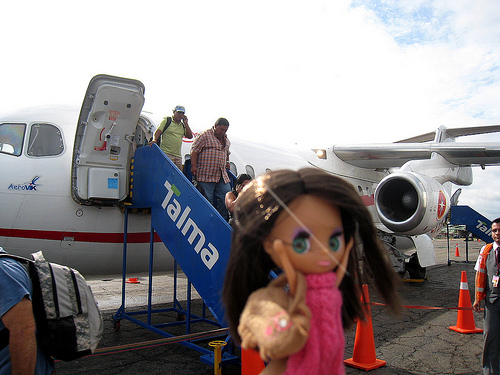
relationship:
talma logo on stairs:
[136, 155, 245, 285] [134, 133, 263, 329]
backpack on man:
[141, 118, 187, 165] [154, 103, 194, 172]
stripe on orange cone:
[458, 280, 472, 292] [437, 259, 487, 342]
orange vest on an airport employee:
[470, 223, 499, 309] [473, 215, 500, 366]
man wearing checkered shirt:
[192, 118, 232, 222] [193, 127, 229, 182]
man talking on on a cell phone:
[154, 103, 194, 172] [181, 115, 189, 121]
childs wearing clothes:
[224, 165, 406, 374] [238, 273, 343, 373]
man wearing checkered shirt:
[189, 116, 235, 202] [193, 129, 235, 182]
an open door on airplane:
[70, 74, 145, 207] [0, 69, 497, 340]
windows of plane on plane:
[2, 115, 69, 174] [0, 79, 493, 342]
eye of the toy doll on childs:
[290, 225, 315, 259] [224, 165, 406, 374]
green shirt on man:
[153, 112, 193, 162] [154, 103, 191, 165]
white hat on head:
[169, 105, 188, 122] [167, 103, 194, 126]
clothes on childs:
[238, 273, 343, 373] [224, 165, 406, 374]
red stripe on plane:
[0, 221, 163, 264] [0, 79, 493, 342]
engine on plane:
[376, 172, 463, 235] [296, 113, 496, 267]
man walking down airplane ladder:
[192, 118, 232, 222] [117, 142, 283, 363]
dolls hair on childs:
[222, 165, 398, 345] [224, 165, 406, 374]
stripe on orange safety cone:
[358, 302, 377, 320] [346, 284, 384, 370]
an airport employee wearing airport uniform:
[473, 215, 500, 366] [466, 243, 499, 370]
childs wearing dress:
[224, 165, 406, 374] [249, 273, 350, 373]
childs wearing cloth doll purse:
[217, 165, 406, 374] [237, 271, 312, 359]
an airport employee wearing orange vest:
[473, 211, 499, 367] [474, 247, 492, 310]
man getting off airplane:
[154, 103, 194, 172] [0, 74, 495, 315]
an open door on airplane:
[64, 83, 175, 224] [0, 69, 497, 340]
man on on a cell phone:
[154, 103, 194, 172] [168, 106, 201, 132]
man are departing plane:
[192, 118, 232, 222] [0, 79, 493, 342]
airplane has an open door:
[0, 74, 499, 315] [70, 74, 145, 207]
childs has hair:
[224, 165, 406, 374] [218, 168, 401, 341]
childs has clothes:
[224, 165, 406, 374] [272, 268, 348, 373]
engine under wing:
[365, 172, 465, 235] [344, 125, 497, 245]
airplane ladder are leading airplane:
[117, 142, 283, 363] [0, 74, 499, 315]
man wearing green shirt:
[154, 103, 194, 172] [153, 112, 193, 162]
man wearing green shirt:
[192, 118, 232, 222] [153, 112, 193, 162]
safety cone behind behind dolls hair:
[453, 236, 470, 261] [222, 161, 398, 345]